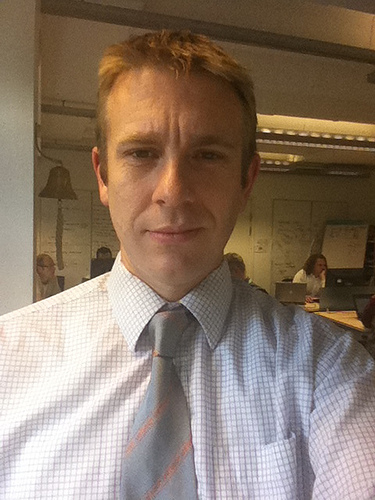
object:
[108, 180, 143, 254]
cheek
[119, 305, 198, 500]
necktie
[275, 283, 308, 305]
computer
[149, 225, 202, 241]
lips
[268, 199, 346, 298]
white board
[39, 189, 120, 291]
white board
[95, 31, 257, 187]
blonde hair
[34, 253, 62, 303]
man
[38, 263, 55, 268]
glasses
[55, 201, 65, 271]
tassel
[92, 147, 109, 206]
ear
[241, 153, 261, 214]
ear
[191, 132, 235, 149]
eyebrow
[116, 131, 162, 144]
eyebrow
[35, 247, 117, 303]
two men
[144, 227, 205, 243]
mouth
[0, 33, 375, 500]
man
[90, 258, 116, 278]
computer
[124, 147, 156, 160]
man's eye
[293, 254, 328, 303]
man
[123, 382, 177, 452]
stripe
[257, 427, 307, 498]
pocket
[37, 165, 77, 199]
bell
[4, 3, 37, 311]
wall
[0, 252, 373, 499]
dress shirt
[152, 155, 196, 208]
nose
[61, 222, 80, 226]
writing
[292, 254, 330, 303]
woman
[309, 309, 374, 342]
desk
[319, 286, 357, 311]
computer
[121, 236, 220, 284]
chin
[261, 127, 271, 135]
lights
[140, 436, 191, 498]
stripe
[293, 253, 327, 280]
hair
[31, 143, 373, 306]
wall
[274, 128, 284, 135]
lights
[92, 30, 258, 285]
head